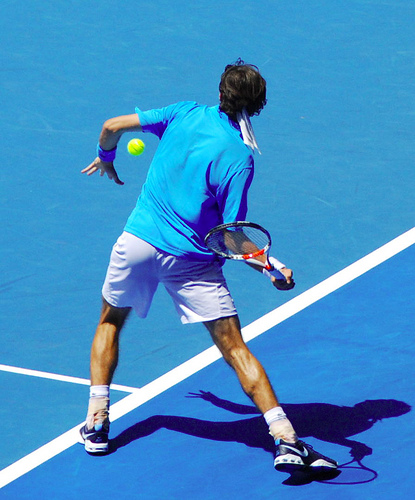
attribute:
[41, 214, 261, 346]
shorts — white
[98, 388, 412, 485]
shadow — player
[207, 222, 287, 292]
tennis racket — black, white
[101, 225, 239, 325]
shorts — white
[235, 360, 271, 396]
muscle — calf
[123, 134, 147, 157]
ball — green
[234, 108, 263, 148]
band — white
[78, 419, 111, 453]
shoe — black and white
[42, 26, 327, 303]
man — playing tennis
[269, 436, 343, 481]
shoe — black, white, tennis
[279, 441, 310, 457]
logo — nike